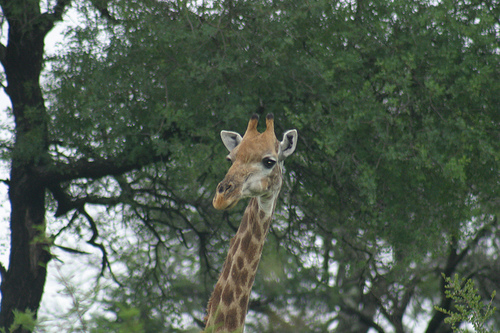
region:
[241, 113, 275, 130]
Horns on a giraffe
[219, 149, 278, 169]
Eyes of a giraffe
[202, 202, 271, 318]
Long neck of a giraffe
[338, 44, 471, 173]
Leaves of a tree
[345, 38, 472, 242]
Tree growing in the background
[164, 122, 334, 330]
A giraffe in the photo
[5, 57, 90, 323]
A tree trunk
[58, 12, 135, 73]
Clouds partially hidden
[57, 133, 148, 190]
A branch on the tree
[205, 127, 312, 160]
White ear of a giraffe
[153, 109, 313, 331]
this is a girafee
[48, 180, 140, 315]
a branch of a tree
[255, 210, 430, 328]
a branch of a tree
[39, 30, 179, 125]
a branch of a tree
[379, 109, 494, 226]
a branch of a tree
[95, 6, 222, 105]
a branch of a tree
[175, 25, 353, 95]
a branch of a tree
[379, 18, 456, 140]
a branch of a tree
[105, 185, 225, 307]
a branch of a tree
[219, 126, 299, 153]
two ears on a giraffe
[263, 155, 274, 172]
the dark left eye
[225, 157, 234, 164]
a partial right eye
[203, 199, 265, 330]
a long spotted neck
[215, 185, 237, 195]
the nostrils of a giraffe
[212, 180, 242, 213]
the mouth and snout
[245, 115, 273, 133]
the cartilage knobs on a giraffe's head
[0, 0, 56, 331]
a tall twisted tree trunk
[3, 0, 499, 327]
foliage behind the giraffe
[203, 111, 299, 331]
a giraffe looking to the left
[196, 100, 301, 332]
tall giraffe with brown spots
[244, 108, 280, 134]
ossicones on giraffe head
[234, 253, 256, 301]
brown spots on giraffe neck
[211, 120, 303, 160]
two giraffe ears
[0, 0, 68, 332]
brown tree trunk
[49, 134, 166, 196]
brown tree branch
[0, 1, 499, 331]
tall green tree behind giraffe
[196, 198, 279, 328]
long giraffe neck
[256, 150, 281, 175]
one giraffe eye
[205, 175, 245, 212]
one giraffe snout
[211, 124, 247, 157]
Ear on a giraffe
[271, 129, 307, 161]
Ear on a giraffe in the air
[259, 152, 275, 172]
Eye on a giraffe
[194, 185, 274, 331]
Neck on a giraffe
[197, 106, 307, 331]
head and neck of a giraffe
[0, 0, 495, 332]
giraffe standing in front of a bunch of trees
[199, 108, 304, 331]
giraffe looking straight ahead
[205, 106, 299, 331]
giraffe with two brown horns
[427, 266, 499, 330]
green leaves of a plant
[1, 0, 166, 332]
brown tree trunk with branches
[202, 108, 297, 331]
a giraffe looking downwards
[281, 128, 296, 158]
left ear of a giraffe